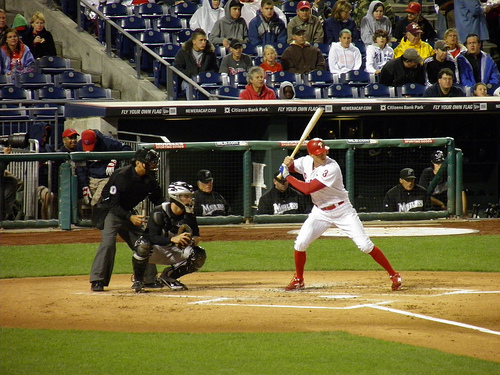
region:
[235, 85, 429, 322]
a man with a baseball bat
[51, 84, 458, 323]
a baseball game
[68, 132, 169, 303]
the umpire for the game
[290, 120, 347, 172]
red baseball helmet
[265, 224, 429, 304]
red knee high socks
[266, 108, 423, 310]
a man in a red and white uniform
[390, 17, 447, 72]
a man in a yellow shirt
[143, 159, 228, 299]
a mna with a black and white helmet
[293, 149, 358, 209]
a shirt with number three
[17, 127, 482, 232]
a green fence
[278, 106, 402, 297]
man holding a baseball bat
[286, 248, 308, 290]
red socks and shoes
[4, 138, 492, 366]
baseball players on field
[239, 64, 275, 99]
person sitting down in stadium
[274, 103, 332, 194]
red baseball cap and brown bat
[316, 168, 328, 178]
number three is in the photo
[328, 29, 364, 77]
person wearing white clothing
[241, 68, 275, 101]
women wearing a red hoodie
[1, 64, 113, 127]
blue seats in stadium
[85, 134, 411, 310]
three baseball players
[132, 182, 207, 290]
catcher behind home plate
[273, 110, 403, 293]
man holding baseball bat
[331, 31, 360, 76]
person wearing white sweatshirt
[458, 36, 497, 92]
man watching baseball game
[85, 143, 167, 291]
umpire waiting for pitch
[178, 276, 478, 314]
home plate of baseball field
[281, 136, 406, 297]
man wearing white and red uniform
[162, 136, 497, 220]
baseball team dug out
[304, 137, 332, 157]
red plastic batting helmet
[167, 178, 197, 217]
black and white catchers helmet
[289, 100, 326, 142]
Top of bat in man's hand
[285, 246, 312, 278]
Man wears red socks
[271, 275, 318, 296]
Man wears red and white sneakers.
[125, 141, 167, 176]
Man wears black helmet.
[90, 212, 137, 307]
Man wears grey pants.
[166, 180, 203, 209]
Man wheres white and black helmet.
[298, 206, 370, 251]
Man wears white pants.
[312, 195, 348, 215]
Man wears red belt.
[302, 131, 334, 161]
Man wear red helmet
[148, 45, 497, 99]
Fan's watch from bleechers.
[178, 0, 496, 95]
Spectators in the stands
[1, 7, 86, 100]
Spectators in the stands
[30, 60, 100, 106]
Blue seats in the stands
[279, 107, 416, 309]
The player at home plate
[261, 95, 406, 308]
The player holding a baseball bat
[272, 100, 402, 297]
The player wearing a red helmet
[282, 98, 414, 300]
The player wearing red socks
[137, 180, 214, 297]
The catcher behind the batter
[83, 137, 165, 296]
The umpire behind the catcher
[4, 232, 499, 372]
the green grass on the ground